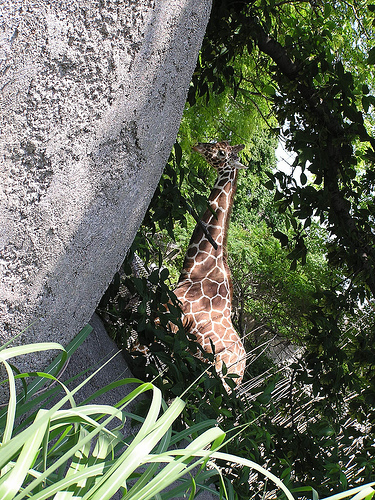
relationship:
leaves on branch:
[262, 123, 347, 274] [245, 3, 295, 71]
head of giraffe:
[194, 131, 251, 177] [166, 134, 273, 394]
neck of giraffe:
[186, 172, 244, 256] [166, 134, 273, 394]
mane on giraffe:
[225, 172, 241, 280] [166, 134, 273, 394]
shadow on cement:
[135, 1, 213, 276] [2, 0, 214, 395]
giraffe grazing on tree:
[166, 134, 273, 394] [168, 143, 210, 206]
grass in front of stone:
[0, 338, 276, 498] [2, 0, 214, 395]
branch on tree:
[245, 3, 295, 71] [221, 6, 374, 218]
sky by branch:
[278, 143, 317, 184] [245, 3, 295, 71]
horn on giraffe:
[232, 149, 244, 161] [166, 134, 273, 394]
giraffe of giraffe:
[166, 134, 273, 394] [166, 134, 273, 394]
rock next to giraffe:
[2, 0, 214, 395] [166, 134, 273, 394]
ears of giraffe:
[222, 143, 250, 172] [166, 134, 273, 394]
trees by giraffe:
[221, 6, 374, 218] [166, 134, 273, 394]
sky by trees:
[278, 143, 317, 184] [278, 50, 368, 242]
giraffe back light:
[166, 134, 273, 394] [214, 195, 237, 348]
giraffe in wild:
[166, 134, 273, 394] [132, 17, 374, 464]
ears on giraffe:
[222, 143, 250, 172] [166, 134, 273, 394]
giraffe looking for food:
[166, 134, 273, 394] [177, 143, 199, 203]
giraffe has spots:
[166, 134, 273, 394] [192, 253, 222, 331]